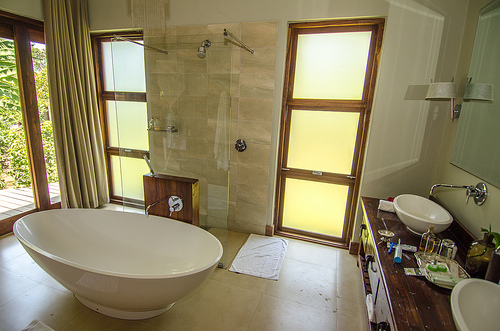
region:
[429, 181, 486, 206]
chrome faucet on wall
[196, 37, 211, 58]
chrome shower head on wall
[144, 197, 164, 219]
faucet for bathtub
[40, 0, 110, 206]
long tan curtain is hanging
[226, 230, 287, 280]
white towel on tan tile floor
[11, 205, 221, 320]
white free-standing bathtub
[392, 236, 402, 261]
blue and white toothbrush on counter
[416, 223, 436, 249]
glass bottle on counter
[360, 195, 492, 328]
counter is wooden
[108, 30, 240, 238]
glass shower enclosure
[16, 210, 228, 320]
a white bathtub on the floor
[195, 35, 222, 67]
a silver shower head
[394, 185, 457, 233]
a white sink on a countertop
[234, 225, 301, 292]
a white towel on the floor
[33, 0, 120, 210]
yellow drapes on the side of the window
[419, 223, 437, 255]
a bottle of soap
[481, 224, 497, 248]
green leaves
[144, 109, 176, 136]
a shower soap holder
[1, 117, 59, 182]
green bush outside the window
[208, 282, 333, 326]
beige linoleum in the bathroom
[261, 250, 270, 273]
the rag is white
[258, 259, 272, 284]
the rag is white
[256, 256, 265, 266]
the rag is white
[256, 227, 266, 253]
the rag is white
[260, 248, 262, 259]
the rag is white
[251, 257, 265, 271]
the rag is white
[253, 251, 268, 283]
the rag is white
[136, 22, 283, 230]
stone wall of shower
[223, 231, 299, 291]
the towel is on the floor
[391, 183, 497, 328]
two white sinks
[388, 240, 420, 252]
toothpaste on the counter top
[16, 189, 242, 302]
bath tub in middle of room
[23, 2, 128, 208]
curtains in the bathroom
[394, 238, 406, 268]
electric toothbrush on the counter top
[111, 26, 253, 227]
shower has three glass walls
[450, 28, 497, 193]
mirrow above the counter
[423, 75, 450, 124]
lamp on the wall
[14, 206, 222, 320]
stand alone porcelain tub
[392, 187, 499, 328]
hid and her sinks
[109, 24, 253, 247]
galssed in shower area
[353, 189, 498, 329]
wooden vanity with open shelf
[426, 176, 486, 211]
extended neck of sink faucet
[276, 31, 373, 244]
frosted glass windows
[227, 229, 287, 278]
white bath mat on floor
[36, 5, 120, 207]
floor to ceiling drapes in corner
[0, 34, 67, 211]
view of outdoor walkway and shrubs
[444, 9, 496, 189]
large mirror over the vanity